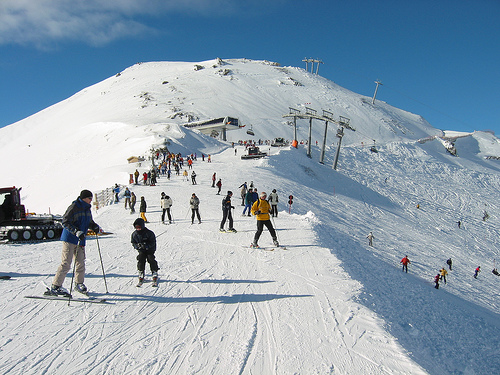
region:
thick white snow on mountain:
[132, 251, 327, 363]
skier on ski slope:
[73, 180, 109, 301]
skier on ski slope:
[130, 221, 162, 276]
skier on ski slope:
[134, 194, 148, 214]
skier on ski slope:
[159, 187, 174, 221]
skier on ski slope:
[189, 184, 197, 219]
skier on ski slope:
[220, 195, 237, 233]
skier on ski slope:
[254, 191, 273, 244]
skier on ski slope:
[189, 170, 194, 184]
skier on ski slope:
[395, 250, 407, 265]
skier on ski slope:
[191, 191, 203, 232]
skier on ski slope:
[132, 189, 139, 215]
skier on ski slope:
[402, 249, 409, 266]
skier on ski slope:
[430, 270, 447, 294]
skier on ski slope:
[472, 266, 481, 281]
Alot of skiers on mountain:
[32, 88, 499, 358]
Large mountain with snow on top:
[4, 51, 499, 372]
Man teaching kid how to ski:
[23, 179, 125, 324]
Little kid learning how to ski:
[124, 211, 179, 311]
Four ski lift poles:
[282, 93, 364, 170]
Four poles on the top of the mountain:
[298, 45, 403, 120]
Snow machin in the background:
[1, 181, 78, 261]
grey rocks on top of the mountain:
[183, 47, 315, 103]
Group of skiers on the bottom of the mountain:
[379, 240, 499, 314]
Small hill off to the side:
[429, 83, 499, 188]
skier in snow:
[40, 189, 101, 296]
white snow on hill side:
[34, 10, 87, 51]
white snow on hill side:
[407, 26, 440, 72]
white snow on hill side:
[334, 34, 373, 70]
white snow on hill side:
[340, 18, 390, 65]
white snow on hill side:
[28, 21, 69, 43]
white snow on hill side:
[124, 5, 166, 43]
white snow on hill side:
[251, 15, 287, 37]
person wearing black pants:
[126, 221, 161, 283]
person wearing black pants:
[219, 191, 236, 235]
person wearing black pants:
[248, 196, 281, 247]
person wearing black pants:
[188, 197, 203, 226]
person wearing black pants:
[161, 195, 174, 222]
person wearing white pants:
[52, 190, 100, 297]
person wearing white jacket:
[188, 194, 203, 225]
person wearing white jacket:
[158, 192, 173, 222]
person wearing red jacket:
[400, 256, 410, 273]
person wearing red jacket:
[473, 266, 483, 279]